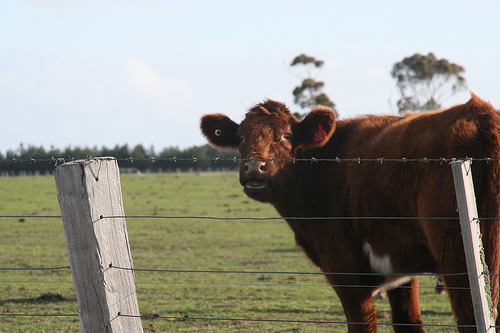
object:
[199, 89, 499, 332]
cow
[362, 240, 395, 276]
patch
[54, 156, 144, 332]
post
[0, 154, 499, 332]
fence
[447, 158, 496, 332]
post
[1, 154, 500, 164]
wire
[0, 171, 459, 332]
field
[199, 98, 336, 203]
head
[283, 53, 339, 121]
tree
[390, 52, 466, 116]
tree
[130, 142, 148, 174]
tree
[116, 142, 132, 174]
tree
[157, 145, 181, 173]
tree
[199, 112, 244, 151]
ear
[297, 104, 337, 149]
ear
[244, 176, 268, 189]
mouth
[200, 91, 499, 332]
fur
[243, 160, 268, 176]
nose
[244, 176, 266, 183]
lip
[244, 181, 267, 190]
lip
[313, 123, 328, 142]
tag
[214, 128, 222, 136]
button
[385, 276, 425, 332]
leg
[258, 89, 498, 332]
side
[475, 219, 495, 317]
moss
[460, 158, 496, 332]
side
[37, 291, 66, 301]
pile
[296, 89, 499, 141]
back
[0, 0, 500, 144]
sky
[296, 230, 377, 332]
leg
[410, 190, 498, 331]
leg